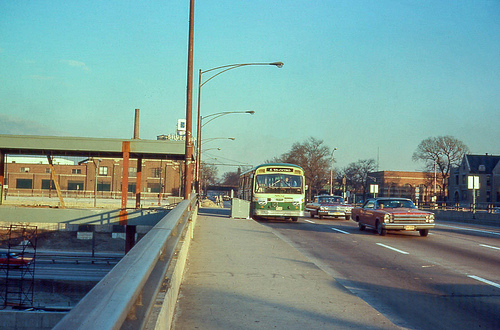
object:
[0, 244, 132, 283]
road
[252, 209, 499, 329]
street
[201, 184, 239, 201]
bus stop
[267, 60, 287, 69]
street lights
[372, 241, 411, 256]
lines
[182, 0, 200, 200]
utility pole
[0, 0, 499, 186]
sky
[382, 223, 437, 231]
bumper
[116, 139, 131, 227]
beam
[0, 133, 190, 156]
roof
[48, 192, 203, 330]
railing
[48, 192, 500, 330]
bridge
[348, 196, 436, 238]
car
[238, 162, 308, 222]
bus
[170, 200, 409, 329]
sidewalk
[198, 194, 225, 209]
construction area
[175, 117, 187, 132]
sign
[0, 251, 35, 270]
car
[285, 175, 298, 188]
driver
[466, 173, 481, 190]
sign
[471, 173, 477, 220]
pole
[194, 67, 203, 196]
lamp post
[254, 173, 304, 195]
windshield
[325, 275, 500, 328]
shadow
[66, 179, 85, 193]
window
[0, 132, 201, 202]
building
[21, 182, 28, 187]
glass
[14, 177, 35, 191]
window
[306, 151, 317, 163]
leaves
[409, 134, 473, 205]
tree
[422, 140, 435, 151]
leaves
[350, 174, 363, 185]
leaves